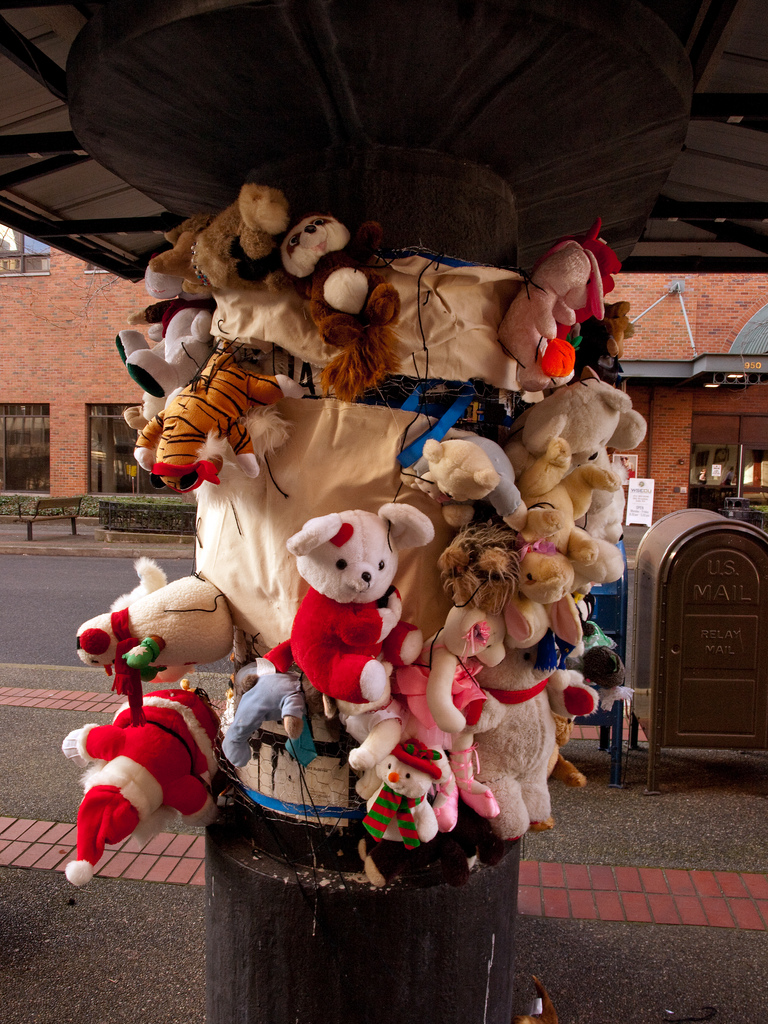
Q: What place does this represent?
A: It represents the sidewalk.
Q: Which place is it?
A: It is a sidewalk.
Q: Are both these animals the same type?
A: No, they are tigers and penguins.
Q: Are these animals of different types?
A: Yes, they are tigers and penguins.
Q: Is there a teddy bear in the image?
A: Yes, there is a teddy bear.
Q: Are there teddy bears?
A: Yes, there is a teddy bear.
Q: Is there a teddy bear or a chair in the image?
A: Yes, there is a teddy bear.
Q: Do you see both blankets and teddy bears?
A: No, there is a teddy bear but no blankets.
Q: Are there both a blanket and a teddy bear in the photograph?
A: No, there is a teddy bear but no blankets.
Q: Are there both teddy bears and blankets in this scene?
A: No, there is a teddy bear but no blankets.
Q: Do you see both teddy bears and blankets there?
A: No, there is a teddy bear but no blankets.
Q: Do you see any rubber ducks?
A: No, there are no rubber ducks.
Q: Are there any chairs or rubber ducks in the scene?
A: No, there are no rubber ducks or chairs.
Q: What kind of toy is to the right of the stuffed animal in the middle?
A: The toy is a teddy bear.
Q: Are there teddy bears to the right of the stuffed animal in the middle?
A: Yes, there is a teddy bear to the right of the stuffed animal.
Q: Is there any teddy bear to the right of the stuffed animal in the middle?
A: Yes, there is a teddy bear to the right of the stuffed animal.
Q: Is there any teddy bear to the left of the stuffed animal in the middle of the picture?
A: No, the teddy bear is to the right of the stuffed animal.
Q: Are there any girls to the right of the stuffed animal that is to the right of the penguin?
A: No, there is a teddy bear to the right of the stuffed animal.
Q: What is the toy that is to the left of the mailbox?
A: The toy is a teddy bear.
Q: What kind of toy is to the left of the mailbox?
A: The toy is a teddy bear.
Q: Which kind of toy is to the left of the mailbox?
A: The toy is a teddy bear.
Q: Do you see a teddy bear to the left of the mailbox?
A: Yes, there is a teddy bear to the left of the mailbox.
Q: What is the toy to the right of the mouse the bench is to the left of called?
A: The toy is a teddy bear.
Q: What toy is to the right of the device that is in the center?
A: The toy is a teddy bear.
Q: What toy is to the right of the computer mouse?
A: The toy is a teddy bear.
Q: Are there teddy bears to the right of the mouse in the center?
A: Yes, there is a teddy bear to the right of the mouse.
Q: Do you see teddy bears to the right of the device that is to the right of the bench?
A: Yes, there is a teddy bear to the right of the mouse.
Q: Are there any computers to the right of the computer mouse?
A: No, there is a teddy bear to the right of the computer mouse.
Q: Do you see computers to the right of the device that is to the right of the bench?
A: No, there is a teddy bear to the right of the computer mouse.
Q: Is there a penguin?
A: Yes, there is a penguin.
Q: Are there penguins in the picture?
A: Yes, there is a penguin.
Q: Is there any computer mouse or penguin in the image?
A: Yes, there is a penguin.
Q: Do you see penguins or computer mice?
A: Yes, there is a penguin.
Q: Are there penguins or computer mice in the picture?
A: Yes, there is a penguin.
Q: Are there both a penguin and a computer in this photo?
A: No, there is a penguin but no computers.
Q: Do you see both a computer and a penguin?
A: No, there is a penguin but no computers.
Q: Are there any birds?
A: No, there are no birds.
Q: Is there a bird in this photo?
A: No, there are no birds.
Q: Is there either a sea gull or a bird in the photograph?
A: No, there are no birds or seagulls.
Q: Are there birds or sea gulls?
A: No, there are no birds or sea gulls.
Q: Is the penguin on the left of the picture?
A: Yes, the penguin is on the left of the image.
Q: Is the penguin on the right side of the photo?
A: No, the penguin is on the left of the image.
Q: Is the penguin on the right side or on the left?
A: The penguin is on the left of the image.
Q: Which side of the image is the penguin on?
A: The penguin is on the left of the image.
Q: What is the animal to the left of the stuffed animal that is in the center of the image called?
A: The animal is a penguin.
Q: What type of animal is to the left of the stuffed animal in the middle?
A: The animal is a penguin.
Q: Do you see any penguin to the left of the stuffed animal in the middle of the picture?
A: Yes, there is a penguin to the left of the stuffed animal.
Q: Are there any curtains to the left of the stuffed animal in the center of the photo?
A: No, there is a penguin to the left of the stuffed animal.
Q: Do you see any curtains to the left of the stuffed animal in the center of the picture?
A: No, there is a penguin to the left of the stuffed animal.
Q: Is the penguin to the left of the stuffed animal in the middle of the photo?
A: Yes, the penguin is to the left of the stuffed animal.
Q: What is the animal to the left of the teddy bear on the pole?
A: The animal is a penguin.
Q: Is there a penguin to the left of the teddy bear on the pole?
A: Yes, there is a penguin to the left of the teddy bear.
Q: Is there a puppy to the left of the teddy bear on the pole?
A: No, there is a penguin to the left of the teddy bear.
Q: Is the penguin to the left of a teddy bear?
A: Yes, the penguin is to the left of a teddy bear.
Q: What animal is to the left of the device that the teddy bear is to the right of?
A: The animal is a penguin.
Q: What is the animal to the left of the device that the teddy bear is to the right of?
A: The animal is a penguin.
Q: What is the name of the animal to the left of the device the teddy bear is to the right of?
A: The animal is a penguin.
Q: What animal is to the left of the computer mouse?
A: The animal is a penguin.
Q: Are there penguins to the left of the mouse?
A: Yes, there is a penguin to the left of the mouse.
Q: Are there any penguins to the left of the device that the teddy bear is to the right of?
A: Yes, there is a penguin to the left of the mouse.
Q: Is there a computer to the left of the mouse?
A: No, there is a penguin to the left of the mouse.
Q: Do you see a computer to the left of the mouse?
A: No, there is a penguin to the left of the mouse.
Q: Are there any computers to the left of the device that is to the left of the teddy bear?
A: No, there is a penguin to the left of the mouse.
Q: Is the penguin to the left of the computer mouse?
A: Yes, the penguin is to the left of the computer mouse.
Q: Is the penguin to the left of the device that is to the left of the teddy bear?
A: Yes, the penguin is to the left of the computer mouse.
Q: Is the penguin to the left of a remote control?
A: No, the penguin is to the left of the computer mouse.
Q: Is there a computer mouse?
A: Yes, there is a computer mouse.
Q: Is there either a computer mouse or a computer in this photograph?
A: Yes, there is a computer mouse.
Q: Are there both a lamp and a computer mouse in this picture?
A: No, there is a computer mouse but no lamps.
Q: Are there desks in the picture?
A: No, there are no desks.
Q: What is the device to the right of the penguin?
A: The device is a computer mouse.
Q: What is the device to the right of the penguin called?
A: The device is a computer mouse.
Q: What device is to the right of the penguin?
A: The device is a computer mouse.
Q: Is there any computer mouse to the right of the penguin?
A: Yes, there is a computer mouse to the right of the penguin.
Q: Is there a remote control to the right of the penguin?
A: No, there is a computer mouse to the right of the penguin.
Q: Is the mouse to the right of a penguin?
A: Yes, the mouse is to the right of a penguin.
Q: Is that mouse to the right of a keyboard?
A: No, the mouse is to the right of a penguin.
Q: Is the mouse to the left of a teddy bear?
A: Yes, the mouse is to the left of a teddy bear.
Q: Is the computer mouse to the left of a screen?
A: No, the computer mouse is to the left of a teddy bear.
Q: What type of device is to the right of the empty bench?
A: The device is a computer mouse.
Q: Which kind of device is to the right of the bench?
A: The device is a computer mouse.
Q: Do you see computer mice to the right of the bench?
A: Yes, there is a computer mouse to the right of the bench.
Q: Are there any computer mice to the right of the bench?
A: Yes, there is a computer mouse to the right of the bench.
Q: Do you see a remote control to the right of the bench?
A: No, there is a computer mouse to the right of the bench.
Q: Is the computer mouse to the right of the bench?
A: Yes, the computer mouse is to the right of the bench.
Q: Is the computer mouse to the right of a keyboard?
A: No, the computer mouse is to the right of the bench.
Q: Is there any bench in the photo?
A: Yes, there is a bench.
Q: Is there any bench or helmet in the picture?
A: Yes, there is a bench.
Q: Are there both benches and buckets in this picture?
A: No, there is a bench but no buckets.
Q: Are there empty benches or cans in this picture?
A: Yes, there is an empty bench.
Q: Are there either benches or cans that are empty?
A: Yes, the bench is empty.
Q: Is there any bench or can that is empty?
A: Yes, the bench is empty.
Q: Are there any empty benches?
A: Yes, there is an empty bench.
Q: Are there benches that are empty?
A: Yes, there is a bench that is empty.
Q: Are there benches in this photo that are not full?
A: Yes, there is a empty bench.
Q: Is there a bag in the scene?
A: No, there are no bags.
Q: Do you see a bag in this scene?
A: No, there are no bags.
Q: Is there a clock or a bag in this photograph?
A: No, there are no bags or clocks.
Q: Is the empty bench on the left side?
A: Yes, the bench is on the left of the image.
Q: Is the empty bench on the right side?
A: No, the bench is on the left of the image.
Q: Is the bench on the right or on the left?
A: The bench is on the left of the image.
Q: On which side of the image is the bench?
A: The bench is on the left of the image.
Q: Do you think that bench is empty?
A: Yes, the bench is empty.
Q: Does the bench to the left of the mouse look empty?
A: Yes, the bench is empty.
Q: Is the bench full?
A: No, the bench is empty.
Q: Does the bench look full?
A: No, the bench is empty.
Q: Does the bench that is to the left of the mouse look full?
A: No, the bench is empty.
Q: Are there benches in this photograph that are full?
A: No, there is a bench but it is empty.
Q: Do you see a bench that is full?
A: No, there is a bench but it is empty.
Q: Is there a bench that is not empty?
A: No, there is a bench but it is empty.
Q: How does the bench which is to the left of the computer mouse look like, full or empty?
A: The bench is empty.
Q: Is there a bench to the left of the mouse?
A: Yes, there is a bench to the left of the mouse.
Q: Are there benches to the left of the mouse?
A: Yes, there is a bench to the left of the mouse.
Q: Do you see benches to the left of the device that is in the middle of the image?
A: Yes, there is a bench to the left of the mouse.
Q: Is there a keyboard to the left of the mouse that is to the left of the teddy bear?
A: No, there is a bench to the left of the computer mouse.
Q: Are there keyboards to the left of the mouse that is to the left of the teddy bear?
A: No, there is a bench to the left of the computer mouse.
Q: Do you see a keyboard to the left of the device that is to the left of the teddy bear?
A: No, there is a bench to the left of the computer mouse.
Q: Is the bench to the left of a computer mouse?
A: Yes, the bench is to the left of a computer mouse.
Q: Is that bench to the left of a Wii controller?
A: No, the bench is to the left of a computer mouse.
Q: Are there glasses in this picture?
A: No, there are no glasses.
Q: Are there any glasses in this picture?
A: No, there are no glasses.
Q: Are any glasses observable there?
A: No, there are no glasses.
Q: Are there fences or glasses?
A: No, there are no glasses or fences.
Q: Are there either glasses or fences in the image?
A: No, there are no glasses or fences.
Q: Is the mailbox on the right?
A: Yes, the mailbox is on the right of the image.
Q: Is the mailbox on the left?
A: No, the mailbox is on the right of the image.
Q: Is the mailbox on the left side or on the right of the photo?
A: The mailbox is on the right of the image.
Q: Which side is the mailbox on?
A: The mailbox is on the right of the image.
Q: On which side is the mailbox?
A: The mailbox is on the right of the image.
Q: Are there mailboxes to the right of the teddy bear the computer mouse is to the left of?
A: Yes, there is a mailbox to the right of the teddy bear.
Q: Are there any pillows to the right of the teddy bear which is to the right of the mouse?
A: No, there is a mailbox to the right of the teddy bear.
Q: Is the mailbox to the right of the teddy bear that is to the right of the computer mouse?
A: Yes, the mailbox is to the right of the teddy bear.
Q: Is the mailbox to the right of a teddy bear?
A: Yes, the mailbox is to the right of a teddy bear.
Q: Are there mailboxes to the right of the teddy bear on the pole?
A: Yes, there is a mailbox to the right of the teddy bear.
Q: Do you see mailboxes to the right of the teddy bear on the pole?
A: Yes, there is a mailbox to the right of the teddy bear.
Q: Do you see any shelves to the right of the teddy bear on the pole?
A: No, there is a mailbox to the right of the teddy bear.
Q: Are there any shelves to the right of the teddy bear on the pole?
A: No, there is a mailbox to the right of the teddy bear.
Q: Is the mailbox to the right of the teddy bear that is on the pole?
A: Yes, the mailbox is to the right of the teddy bear.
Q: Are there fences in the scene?
A: No, there are no fences.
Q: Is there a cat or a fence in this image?
A: No, there are no fences or cats.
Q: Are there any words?
A: Yes, there are words.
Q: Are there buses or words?
A: Yes, there are words.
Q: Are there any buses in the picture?
A: No, there are no buses.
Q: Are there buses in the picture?
A: No, there are no buses.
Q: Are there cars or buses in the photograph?
A: No, there are no buses or cars.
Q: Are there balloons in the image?
A: No, there are no balloons.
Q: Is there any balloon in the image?
A: No, there are no balloons.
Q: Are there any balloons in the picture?
A: No, there are no balloons.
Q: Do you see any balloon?
A: No, there are no balloons.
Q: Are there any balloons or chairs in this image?
A: No, there are no balloons or chairs.